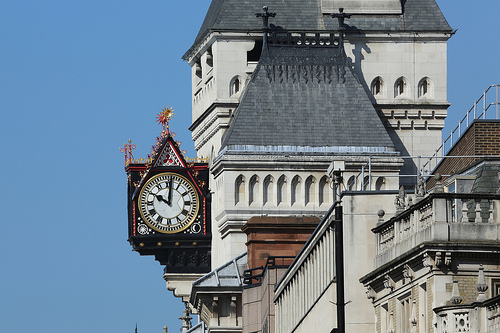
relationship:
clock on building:
[136, 171, 204, 231] [123, 0, 492, 328]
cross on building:
[252, 1, 279, 41] [123, 0, 492, 328]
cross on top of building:
[252, 1, 279, 41] [123, 0, 492, 328]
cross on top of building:
[328, 3, 352, 31] [123, 0, 492, 328]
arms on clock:
[165, 180, 176, 204] [132, 168, 202, 238]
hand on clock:
[154, 190, 170, 206] [132, 168, 202, 238]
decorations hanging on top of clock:
[154, 100, 174, 133] [132, 168, 202, 238]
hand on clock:
[146, 190, 171, 206] [110, 149, 216, 234]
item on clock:
[149, 98, 183, 127] [124, 148, 206, 245]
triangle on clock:
[148, 129, 189, 167] [128, 134, 211, 243]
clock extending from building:
[136, 171, 198, 235] [126, 110, 403, 327]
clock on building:
[136, 171, 198, 235] [242, 137, 460, 329]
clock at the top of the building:
[136, 171, 198, 235] [119, 14, 410, 252]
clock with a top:
[136, 171, 198, 235] [137, 103, 187, 162]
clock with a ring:
[136, 171, 198, 235] [137, 171, 199, 231]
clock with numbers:
[136, 171, 198, 235] [145, 177, 195, 226]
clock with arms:
[136, 171, 198, 235] [154, 180, 179, 208]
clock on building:
[136, 171, 198, 235] [91, 2, 498, 304]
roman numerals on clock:
[129, 161, 201, 240] [124, 150, 239, 270]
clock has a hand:
[136, 171, 198, 235] [146, 190, 171, 206]